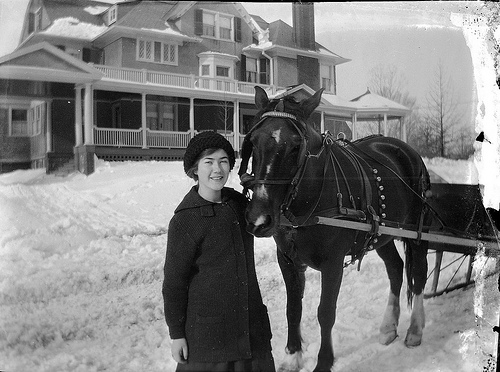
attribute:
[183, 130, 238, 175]
knit beanie — black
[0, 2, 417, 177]
large house — in background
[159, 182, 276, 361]
sweater — long, black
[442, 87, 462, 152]
branches — tree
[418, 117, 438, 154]
branches — tree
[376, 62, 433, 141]
branches — tree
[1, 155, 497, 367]
snow — white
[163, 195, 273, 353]
coat — her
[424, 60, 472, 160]
tree — bare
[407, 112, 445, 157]
tree — bare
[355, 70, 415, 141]
tree — bare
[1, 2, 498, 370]
photograph — black and white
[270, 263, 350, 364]
legs — horse's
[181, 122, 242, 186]
hat — her